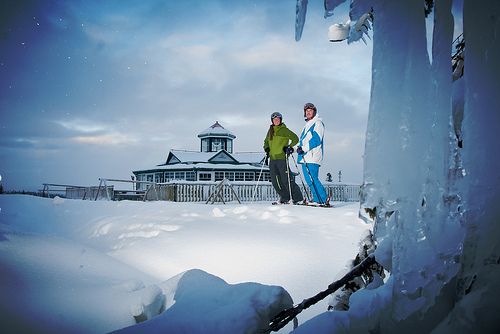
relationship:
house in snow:
[130, 120, 282, 202] [105, 196, 327, 288]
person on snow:
[261, 112, 309, 206] [200, 195, 291, 259]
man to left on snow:
[295, 101, 332, 206] [2, 193, 374, 332]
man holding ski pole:
[295, 101, 332, 206] [299, 142, 329, 206]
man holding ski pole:
[295, 101, 332, 206] [281, 143, 312, 208]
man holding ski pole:
[291, 101, 341, 213] [293, 138, 323, 201]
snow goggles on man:
[301, 102, 316, 112] [293, 98, 333, 207]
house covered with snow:
[130, 120, 282, 202] [2, 193, 374, 332]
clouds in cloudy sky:
[120, 45, 348, 115] [1, 0, 371, 193]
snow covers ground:
[37, 207, 139, 277] [62, 188, 227, 261]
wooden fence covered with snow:
[105, 161, 287, 203] [227, 174, 258, 192]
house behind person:
[128, 120, 277, 201] [252, 106, 304, 206]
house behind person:
[128, 120, 277, 201] [290, 96, 339, 213]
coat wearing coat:
[261, 120, 299, 161] [293, 114, 330, 167]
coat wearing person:
[261, 120, 299, 161] [261, 107, 299, 209]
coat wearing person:
[261, 120, 299, 161] [292, 99, 336, 211]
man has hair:
[295, 101, 332, 206] [303, 104, 310, 115]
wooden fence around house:
[145, 177, 362, 204] [128, 120, 277, 201]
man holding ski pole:
[295, 101, 332, 206] [292, 146, 312, 204]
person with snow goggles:
[261, 112, 301, 207] [270, 112, 280, 119]